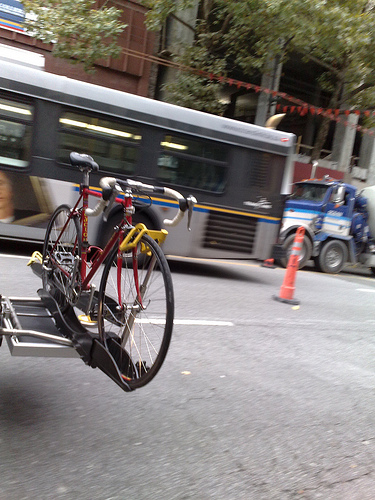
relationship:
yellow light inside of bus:
[0, 99, 192, 152] [7, 62, 284, 262]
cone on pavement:
[270, 223, 307, 303] [0, 253, 373, 497]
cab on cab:
[273, 172, 356, 266] [273, 176, 375, 273]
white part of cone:
[290, 239, 301, 256] [271, 225, 303, 304]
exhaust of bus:
[255, 105, 295, 130] [7, 62, 284, 262]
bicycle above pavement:
[43, 151, 196, 387] [0, 253, 373, 497]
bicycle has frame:
[43, 151, 196, 387] [73, 181, 149, 307]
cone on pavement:
[273, 227, 305, 306] [0, 253, 373, 497]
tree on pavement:
[24, 1, 125, 66] [0, 253, 373, 497]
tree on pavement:
[162, 44, 225, 110] [0, 253, 373, 497]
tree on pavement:
[233, 1, 373, 98] [0, 253, 373, 497]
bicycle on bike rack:
[43, 144, 196, 387] [4, 287, 137, 390]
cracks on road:
[173, 386, 281, 496] [1, 234, 373, 488]